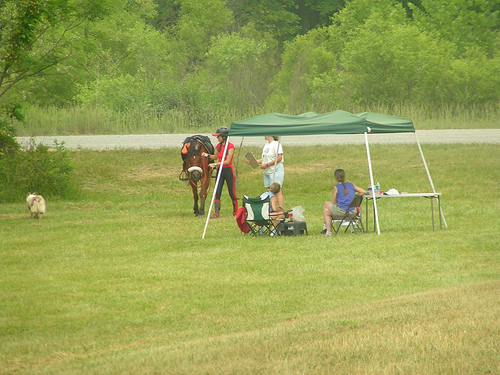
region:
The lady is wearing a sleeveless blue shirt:
[332, 185, 359, 206]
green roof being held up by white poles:
[236, 109, 403, 130]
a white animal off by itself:
[22, 192, 50, 215]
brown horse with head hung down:
[182, 135, 205, 217]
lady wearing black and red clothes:
[212, 128, 235, 212]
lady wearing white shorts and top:
[261, 140, 282, 184]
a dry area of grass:
[120, 164, 172, 181]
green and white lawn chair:
[243, 199, 272, 235]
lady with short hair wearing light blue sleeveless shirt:
[262, 186, 278, 198]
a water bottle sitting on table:
[373, 183, 431, 201]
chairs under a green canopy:
[219, 103, 431, 235]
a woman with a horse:
[171, 115, 243, 217]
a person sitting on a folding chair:
[320, 166, 365, 235]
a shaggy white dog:
[17, 190, 50, 218]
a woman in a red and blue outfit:
[206, 122, 239, 214]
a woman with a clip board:
[241, 130, 286, 222]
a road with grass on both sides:
[45, 116, 499, 151]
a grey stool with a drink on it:
[273, 204, 315, 238]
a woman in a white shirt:
[253, 130, 295, 207]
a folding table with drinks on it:
[369, 176, 444, 240]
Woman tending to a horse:
[158, 117, 245, 224]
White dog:
[12, 180, 51, 220]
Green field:
[47, 248, 483, 342]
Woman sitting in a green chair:
[236, 182, 314, 247]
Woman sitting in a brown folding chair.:
[312, 162, 377, 239]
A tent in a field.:
[165, 93, 455, 250]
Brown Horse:
[170, 130, 218, 230]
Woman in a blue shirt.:
[312, 165, 377, 237]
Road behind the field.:
[6, 115, 494, 365]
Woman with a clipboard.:
[235, 107, 304, 233]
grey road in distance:
[5, 130, 496, 142]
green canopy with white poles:
[197, 107, 447, 235]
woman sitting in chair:
[322, 164, 369, 236]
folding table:
[359, 186, 445, 235]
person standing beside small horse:
[180, 122, 240, 217]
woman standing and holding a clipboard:
[241, 125, 281, 215]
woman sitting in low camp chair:
[237, 180, 287, 236]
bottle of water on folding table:
[373, 178, 383, 198]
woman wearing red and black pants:
[212, 163, 239, 215]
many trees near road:
[4, 3, 496, 125]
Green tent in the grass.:
[191, 106, 448, 249]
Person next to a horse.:
[178, 128, 241, 217]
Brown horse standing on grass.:
[174, 128, 216, 223]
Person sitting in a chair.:
[237, 180, 292, 240]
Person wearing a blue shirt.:
[317, 165, 373, 240]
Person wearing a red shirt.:
[206, 126, 242, 226]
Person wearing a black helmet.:
[207, 123, 246, 228]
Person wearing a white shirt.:
[246, 117, 289, 222]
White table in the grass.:
[355, 183, 450, 250]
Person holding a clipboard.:
[238, 126, 295, 208]